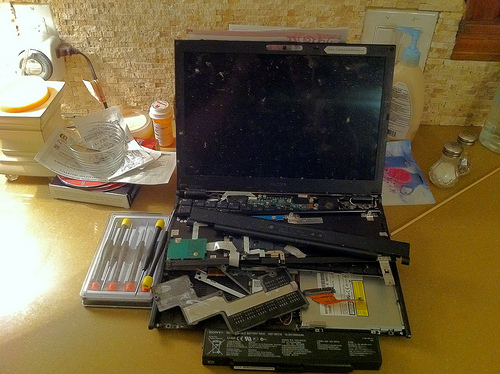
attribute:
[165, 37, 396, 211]
computer — torn apart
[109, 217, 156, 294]
tools — orange, yellow, black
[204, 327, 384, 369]
battery — black, internal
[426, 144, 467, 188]
salt shaker — glass, crystal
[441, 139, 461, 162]
top — silver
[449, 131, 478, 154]
pepper shaker — glass, crystal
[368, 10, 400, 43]
light switch — cream colored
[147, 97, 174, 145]
medicine bottle — orange, prescription, brown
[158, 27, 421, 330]
laptop — opened, old, black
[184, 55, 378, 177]
screen — off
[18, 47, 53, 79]
timer — eletronic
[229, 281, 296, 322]
hard drive — internal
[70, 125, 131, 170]
bowl — glass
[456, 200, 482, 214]
counter top — yellow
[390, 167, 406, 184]
paper — pink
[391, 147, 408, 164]
paper — blue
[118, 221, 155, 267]
kit — small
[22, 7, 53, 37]
outlets — electrical